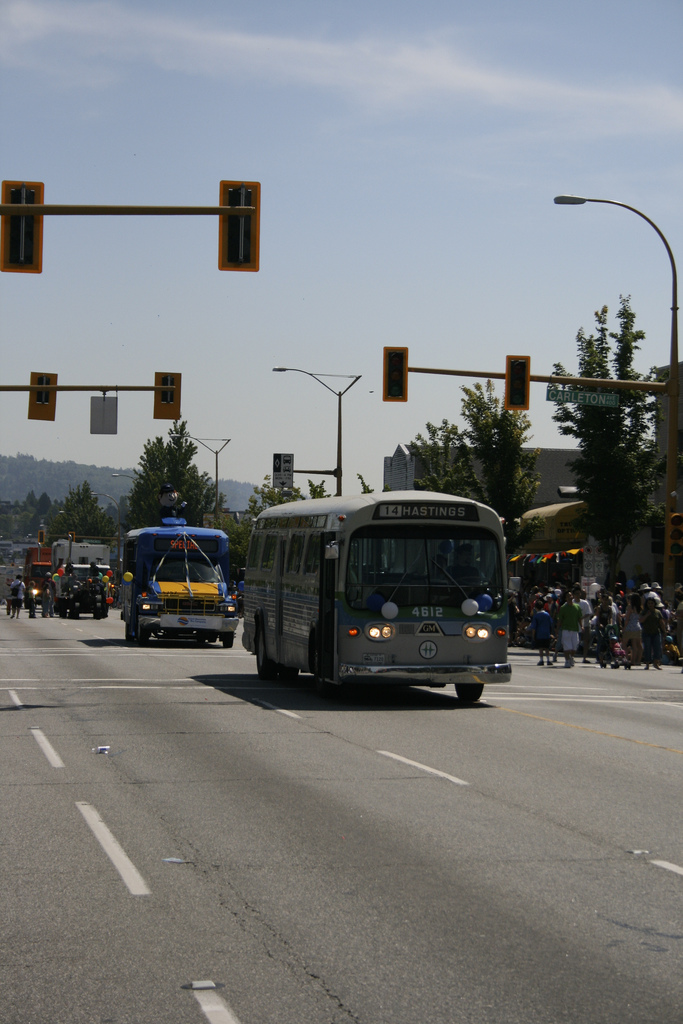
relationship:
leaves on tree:
[420, 419, 443, 447] [408, 375, 547, 553]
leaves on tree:
[459, 382, 486, 408] [408, 375, 547, 553]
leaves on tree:
[522, 445, 539, 476] [408, 375, 547, 553]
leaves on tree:
[170, 414, 196, 452] [121, 413, 230, 528]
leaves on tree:
[137, 414, 198, 468] [121, 413, 230, 528]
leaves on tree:
[130, 466, 157, 494] [121, 413, 230, 528]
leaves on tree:
[199, 471, 229, 514] [121, 413, 230, 528]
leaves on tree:
[129, 436, 159, 494] [121, 413, 230, 528]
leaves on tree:
[40, 507, 64, 529] [43, 479, 116, 539]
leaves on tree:
[64, 480, 104, 516] [43, 479, 116, 539]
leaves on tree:
[83, 491, 104, 512] [43, 479, 116, 539]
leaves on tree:
[94, 516, 118, 534] [43, 479, 116, 539]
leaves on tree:
[129, 436, 159, 494] [125, 414, 226, 524]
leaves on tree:
[137, 414, 198, 468] [125, 414, 226, 524]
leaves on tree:
[199, 471, 229, 514] [125, 414, 226, 524]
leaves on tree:
[199, 471, 225, 502] [125, 414, 226, 524]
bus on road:
[235, 480, 515, 709] [4, 596, 682, 1021]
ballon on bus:
[381, 601, 400, 620] [235, 480, 515, 709]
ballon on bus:
[459, 597, 480, 616] [235, 480, 515, 709]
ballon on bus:
[479, 592, 496, 611] [235, 480, 515, 709]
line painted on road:
[479, 701, 662, 748] [4, 596, 682, 1021]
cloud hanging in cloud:
[0, 0, 683, 496] [0, 0, 683, 496]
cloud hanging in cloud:
[1, 320, 661, 491] [0, 0, 683, 496]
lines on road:
[9, 683, 233, 1022] [0, 608, 683, 1024]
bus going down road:
[235, 480, 515, 709] [4, 596, 682, 1021]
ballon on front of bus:
[461, 599, 478, 616] [235, 480, 515, 709]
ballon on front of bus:
[381, 602, 398, 619] [235, 480, 515, 709]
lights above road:
[378, 348, 533, 413] [4, 596, 682, 1021]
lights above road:
[24, 366, 185, 430] [4, 596, 682, 1021]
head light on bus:
[472, 621, 486, 643] [235, 480, 515, 709]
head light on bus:
[365, 621, 384, 642] [235, 480, 515, 709]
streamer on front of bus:
[154, 524, 219, 582] [120, 484, 244, 648]